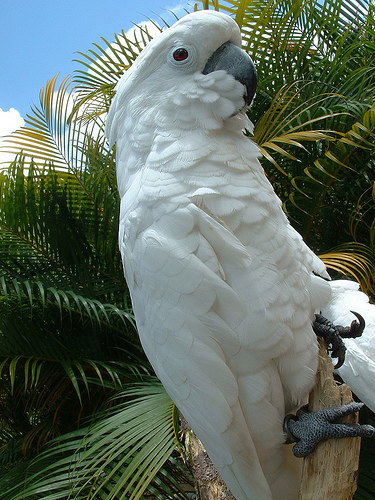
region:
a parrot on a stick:
[99, 5, 373, 498]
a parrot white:
[92, 5, 373, 496]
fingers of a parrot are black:
[280, 291, 372, 473]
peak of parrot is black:
[210, 42, 268, 110]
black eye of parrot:
[167, 43, 194, 67]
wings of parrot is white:
[96, 212, 269, 499]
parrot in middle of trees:
[81, 6, 366, 498]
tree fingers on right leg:
[285, 396, 373, 465]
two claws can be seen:
[320, 305, 373, 378]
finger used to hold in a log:
[288, 308, 373, 467]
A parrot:
[167, 218, 237, 333]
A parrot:
[188, 267, 244, 449]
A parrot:
[209, 357, 230, 405]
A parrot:
[161, 317, 215, 455]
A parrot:
[157, 208, 197, 396]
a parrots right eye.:
[168, 35, 204, 76]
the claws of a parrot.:
[303, 308, 368, 382]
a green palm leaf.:
[69, 361, 190, 498]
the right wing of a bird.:
[119, 170, 284, 496]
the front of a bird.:
[179, 179, 311, 398]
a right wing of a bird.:
[308, 271, 372, 413]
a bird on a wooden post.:
[177, 336, 365, 497]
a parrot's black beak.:
[197, 36, 263, 104]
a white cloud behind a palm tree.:
[1, 107, 47, 181]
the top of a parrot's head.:
[60, 49, 153, 196]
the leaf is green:
[125, 462, 155, 490]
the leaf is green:
[140, 454, 163, 475]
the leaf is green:
[145, 442, 164, 465]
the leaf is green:
[137, 444, 170, 471]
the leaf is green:
[135, 451, 150, 468]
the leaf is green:
[150, 460, 162, 470]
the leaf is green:
[149, 471, 163, 477]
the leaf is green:
[139, 469, 153, 479]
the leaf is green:
[135, 466, 170, 487]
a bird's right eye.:
[168, 44, 207, 74]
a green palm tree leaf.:
[58, 379, 187, 499]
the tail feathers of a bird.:
[208, 356, 321, 499]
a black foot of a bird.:
[279, 396, 372, 455]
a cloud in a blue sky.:
[0, 88, 80, 185]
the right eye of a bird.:
[161, 34, 206, 76]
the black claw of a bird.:
[305, 295, 373, 372]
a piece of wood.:
[187, 327, 365, 497]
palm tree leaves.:
[253, 59, 373, 191]